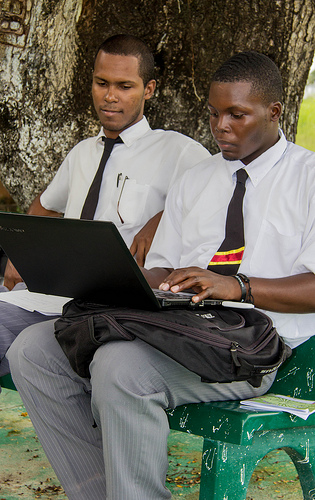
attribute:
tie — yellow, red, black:
[198, 162, 261, 287]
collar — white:
[245, 138, 287, 186]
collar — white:
[225, 160, 241, 179]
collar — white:
[117, 125, 147, 142]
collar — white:
[93, 127, 102, 142]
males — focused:
[3, 33, 313, 498]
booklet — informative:
[239, 393, 312, 423]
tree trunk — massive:
[0, 0, 313, 211]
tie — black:
[76, 136, 123, 221]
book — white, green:
[240, 391, 314, 419]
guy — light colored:
[5, 26, 211, 299]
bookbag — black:
[47, 303, 292, 385]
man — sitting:
[67, 33, 141, 250]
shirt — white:
[0, 115, 213, 314]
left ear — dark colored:
[267, 99, 282, 122]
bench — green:
[1, 251, 305, 496]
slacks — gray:
[1, 280, 64, 385]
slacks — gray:
[3, 304, 285, 497]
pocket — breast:
[101, 177, 151, 231]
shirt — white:
[142, 126, 304, 351]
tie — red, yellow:
[205, 165, 247, 278]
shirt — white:
[47, 114, 214, 266]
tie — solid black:
[77, 130, 124, 221]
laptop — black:
[0, 210, 254, 312]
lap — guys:
[5, 305, 276, 375]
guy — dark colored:
[5, 51, 313, 498]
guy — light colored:
[0, 34, 210, 359]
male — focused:
[5, 51, 313, 497]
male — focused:
[0, 34, 213, 377]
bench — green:
[0, 335, 313, 499]